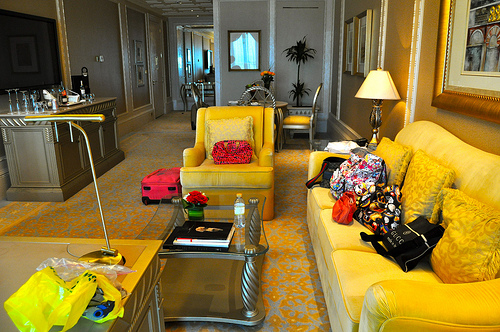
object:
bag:
[0, 253, 129, 330]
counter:
[0, 234, 167, 331]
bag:
[141, 167, 183, 205]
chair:
[180, 105, 275, 223]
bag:
[211, 139, 254, 165]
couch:
[306, 120, 500, 332]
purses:
[357, 213, 446, 274]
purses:
[332, 192, 358, 225]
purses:
[306, 156, 347, 190]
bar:
[1, 95, 125, 203]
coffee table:
[133, 193, 270, 326]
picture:
[429, 0, 499, 128]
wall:
[322, 0, 500, 236]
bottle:
[232, 192, 246, 229]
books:
[162, 220, 237, 252]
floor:
[1, 108, 471, 331]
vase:
[264, 80, 271, 98]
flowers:
[259, 70, 275, 76]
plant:
[279, 34, 316, 118]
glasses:
[5, 88, 15, 115]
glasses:
[12, 87, 20, 114]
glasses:
[19, 89, 31, 116]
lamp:
[352, 70, 400, 151]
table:
[309, 137, 374, 152]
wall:
[208, 0, 336, 140]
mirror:
[227, 30, 262, 73]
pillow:
[202, 115, 257, 161]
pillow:
[368, 136, 412, 191]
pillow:
[395, 148, 456, 226]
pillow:
[430, 186, 499, 283]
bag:
[328, 148, 388, 201]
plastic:
[34, 257, 136, 300]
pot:
[285, 104, 320, 140]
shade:
[354, 70, 402, 101]